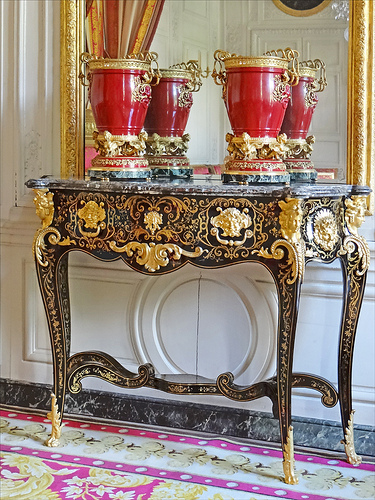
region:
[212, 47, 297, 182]
red, gold and black vase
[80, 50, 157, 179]
red, gold and black vase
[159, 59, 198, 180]
reflection of red, gold and black vase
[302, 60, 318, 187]
reflection of red, gold and black vase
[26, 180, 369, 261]
black and gold desk top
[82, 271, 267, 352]
white decorative wall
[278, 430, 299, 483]
gold desk footer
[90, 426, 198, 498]
pink, yellow and white rug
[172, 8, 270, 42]
reflection in mirror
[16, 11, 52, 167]
white decorative wall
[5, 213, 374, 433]
The wall is white.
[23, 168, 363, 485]
The table is black and gold.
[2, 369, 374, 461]
The baseboard is marble.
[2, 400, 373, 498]
The floor is white, red and gold.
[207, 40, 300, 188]
The vases are red and gold.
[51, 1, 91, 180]
The mirror frame is gold.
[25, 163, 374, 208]
The table top is marble.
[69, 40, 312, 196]
Two vases on the table.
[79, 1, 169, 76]
Red and yellow curtain.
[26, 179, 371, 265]
Gold sculptures in the table.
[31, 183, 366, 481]
a grey and yellow metal table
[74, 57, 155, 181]
a red and yellow vase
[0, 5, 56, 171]
a wooden white wall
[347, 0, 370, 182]
golden trim around mirror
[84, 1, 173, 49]
reflection of curtains in mirror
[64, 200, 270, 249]
yellow design on metal table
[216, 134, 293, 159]
yellow design on red vase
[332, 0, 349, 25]
reflection of chandelier in mirror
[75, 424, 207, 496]
a rug with designs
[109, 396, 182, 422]
black and white floor moulding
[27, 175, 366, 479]
the table is gold and black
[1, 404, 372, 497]
the carpet is red and gold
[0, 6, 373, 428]
the wall is white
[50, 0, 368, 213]
the mirror has a gold frame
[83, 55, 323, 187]
the vases are red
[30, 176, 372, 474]
the table has many details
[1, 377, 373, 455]
the molding is marble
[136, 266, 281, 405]
the wall has a circle design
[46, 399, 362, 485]
the foot of the table is gold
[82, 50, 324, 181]
the vases have gold details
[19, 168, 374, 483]
an ornate side table of gold and black in a house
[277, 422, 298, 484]
gold decorations encase the feet and lower leg of the table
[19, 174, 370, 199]
the top piece of the table seems to be a black marble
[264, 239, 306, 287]
the top of the leg also has a gold decoration in leaf form on it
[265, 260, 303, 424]
down the face of the leg are gold leaves and flowers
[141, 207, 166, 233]
the middle gold decoration seems to be a gold face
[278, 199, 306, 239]
this gold face above the decoration on the top of the leg seems to be a womans face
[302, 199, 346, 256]
each of the faces on the side table is surrounded by gold scroll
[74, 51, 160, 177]
One of 2 red ornate vases on the side table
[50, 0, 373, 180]
the gold framed mirror attached to the wall above the side table